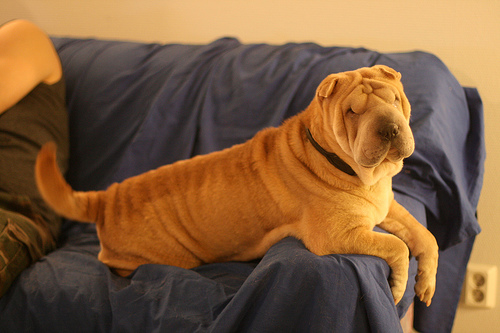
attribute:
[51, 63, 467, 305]
dog — brown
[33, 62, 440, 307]
dog — brown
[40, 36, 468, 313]
dog — large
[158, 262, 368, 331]
couch cover — blue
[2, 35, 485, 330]
couch cover — blue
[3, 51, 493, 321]
cover — blue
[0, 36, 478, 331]
sheet — blue